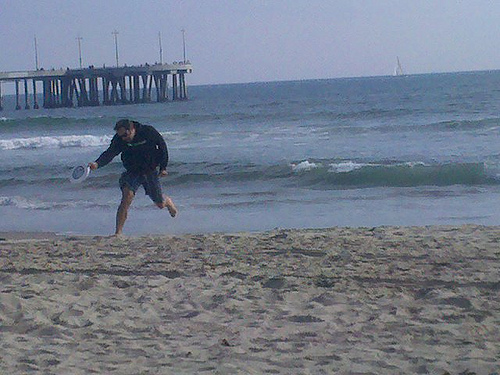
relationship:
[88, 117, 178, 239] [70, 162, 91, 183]
man holding frisbee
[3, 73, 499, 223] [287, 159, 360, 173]
water has ripples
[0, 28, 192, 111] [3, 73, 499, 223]
pier above water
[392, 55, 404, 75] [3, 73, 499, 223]
sail boat on water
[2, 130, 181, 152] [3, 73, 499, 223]
wave on water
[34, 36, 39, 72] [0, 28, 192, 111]
pole on pier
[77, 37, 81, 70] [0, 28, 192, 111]
pole on pier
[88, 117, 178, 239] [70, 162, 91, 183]
man playing with a frisbee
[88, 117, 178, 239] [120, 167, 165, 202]
man wearing shorts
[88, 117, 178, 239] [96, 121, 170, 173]
man wearing a hoodie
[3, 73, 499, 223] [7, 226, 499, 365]
water meets sand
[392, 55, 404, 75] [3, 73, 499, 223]
sail boat in water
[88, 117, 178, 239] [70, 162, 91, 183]
man catching a frisbee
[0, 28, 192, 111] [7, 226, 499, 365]
pier near sand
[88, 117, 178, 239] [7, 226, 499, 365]
man on sand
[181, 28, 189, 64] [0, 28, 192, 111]
pole on pier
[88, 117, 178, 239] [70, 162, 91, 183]
man has frisbee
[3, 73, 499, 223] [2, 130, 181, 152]
water has some wave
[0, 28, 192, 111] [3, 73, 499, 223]
pier over water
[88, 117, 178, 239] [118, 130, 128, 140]
man wearing sunglasses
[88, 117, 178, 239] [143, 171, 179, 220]
man has a left leg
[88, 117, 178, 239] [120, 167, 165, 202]
man wears shorts